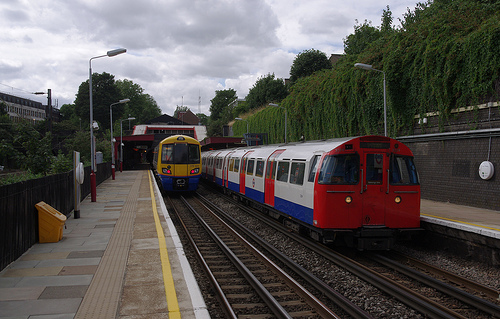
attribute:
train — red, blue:
[197, 133, 422, 251]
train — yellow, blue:
[154, 136, 204, 195]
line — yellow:
[145, 169, 186, 317]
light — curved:
[80, 46, 130, 206]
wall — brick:
[400, 102, 499, 214]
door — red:
[260, 152, 288, 209]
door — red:
[236, 146, 256, 195]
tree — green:
[73, 73, 131, 165]